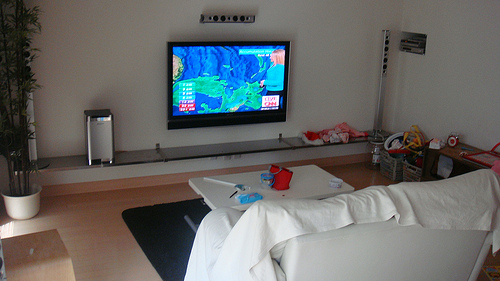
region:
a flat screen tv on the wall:
[160, 36, 293, 132]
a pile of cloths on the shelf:
[297, 113, 365, 158]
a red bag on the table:
[257, 161, 304, 196]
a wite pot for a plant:
[5, 180, 45, 222]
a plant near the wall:
[0, 1, 48, 217]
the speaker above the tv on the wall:
[197, 7, 257, 29]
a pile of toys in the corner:
[373, 124, 428, 188]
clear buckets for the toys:
[376, 153, 424, 183]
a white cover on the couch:
[182, 169, 499, 278]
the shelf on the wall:
[148, 129, 288, 169]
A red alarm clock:
[443, 122, 459, 152]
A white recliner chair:
[145, 150, 495, 276]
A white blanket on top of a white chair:
[175, 170, 495, 251]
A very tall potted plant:
[0, 1, 62, 221]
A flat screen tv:
[155, 35, 290, 132]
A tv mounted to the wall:
[156, 30, 296, 130]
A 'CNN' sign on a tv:
[256, 90, 281, 110]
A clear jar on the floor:
[360, 135, 386, 166]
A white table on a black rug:
[145, 151, 362, 228]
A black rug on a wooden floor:
[105, 185, 211, 280]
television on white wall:
[102, 15, 339, 144]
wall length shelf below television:
[25, 60, 437, 192]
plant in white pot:
[2, 15, 50, 229]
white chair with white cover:
[179, 185, 499, 279]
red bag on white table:
[254, 151, 341, 204]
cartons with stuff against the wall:
[364, 97, 464, 186]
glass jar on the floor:
[347, 125, 395, 188]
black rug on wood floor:
[112, 139, 259, 279]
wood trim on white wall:
[61, 149, 290, 191]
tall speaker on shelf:
[357, 15, 403, 160]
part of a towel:
[341, 208, 383, 228]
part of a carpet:
[136, 204, 164, 225]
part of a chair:
[317, 224, 350, 274]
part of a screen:
[188, 40, 264, 116]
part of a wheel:
[83, 5, 115, 30]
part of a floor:
[71, 209, 123, 264]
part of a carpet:
[133, 195, 185, 240]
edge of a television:
[194, 120, 216, 135]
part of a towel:
[390, 184, 415, 212]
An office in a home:
[148, 22, 367, 275]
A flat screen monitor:
[161, 30, 296, 132]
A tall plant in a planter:
[7, 0, 57, 225]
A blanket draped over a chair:
[299, 206, 474, 271]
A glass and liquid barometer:
[360, 19, 402, 146]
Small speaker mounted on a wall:
[182, 11, 270, 26]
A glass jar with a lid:
[358, 140, 385, 166]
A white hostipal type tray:
[186, 162, 353, 214]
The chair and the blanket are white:
[250, 205, 485, 275]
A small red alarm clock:
[446, 133, 457, 149]